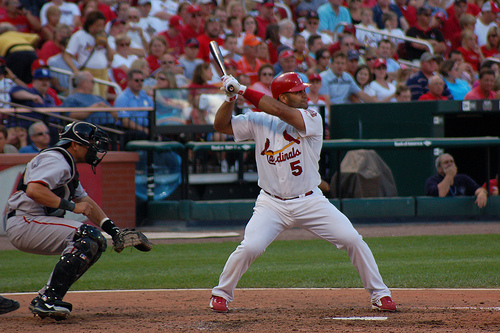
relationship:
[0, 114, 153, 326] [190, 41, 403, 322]
catcher behind baseball player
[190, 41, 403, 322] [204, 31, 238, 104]
baseball player holding bat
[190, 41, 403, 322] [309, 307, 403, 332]
baseball player near home plate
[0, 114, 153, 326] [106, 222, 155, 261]
catcher wearing mitt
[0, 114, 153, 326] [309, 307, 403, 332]
catcher behind home plate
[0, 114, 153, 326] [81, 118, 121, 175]
catcher wearing mask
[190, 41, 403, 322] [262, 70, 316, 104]
baseball player wearing helmet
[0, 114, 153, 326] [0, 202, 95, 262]
catcher wearing pants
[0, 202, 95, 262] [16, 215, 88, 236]
pants have stripe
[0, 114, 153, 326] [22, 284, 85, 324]
catcher wearing shoes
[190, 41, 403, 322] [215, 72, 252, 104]
baseball player wearing gloves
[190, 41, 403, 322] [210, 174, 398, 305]
baseball player wearing pants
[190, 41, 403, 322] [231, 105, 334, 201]
baseball player wearing shirt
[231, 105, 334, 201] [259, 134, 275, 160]
shirt has bird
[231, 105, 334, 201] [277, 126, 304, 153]
shirt has bird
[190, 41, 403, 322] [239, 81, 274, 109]
baseball player wearing wrist band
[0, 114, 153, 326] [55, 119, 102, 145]
catcher has helmet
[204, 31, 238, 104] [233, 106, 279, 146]
bat over shoulder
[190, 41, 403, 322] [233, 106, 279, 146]
baseball player has shoulder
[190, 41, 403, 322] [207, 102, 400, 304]
baseball player wearing uniform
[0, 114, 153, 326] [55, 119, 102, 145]
catcher wearing helmet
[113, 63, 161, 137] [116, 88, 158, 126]
man wearing shirt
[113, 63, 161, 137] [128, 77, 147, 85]
man wearing glasses